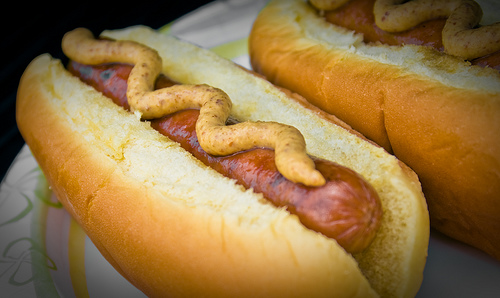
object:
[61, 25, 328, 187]
mustard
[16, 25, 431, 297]
bun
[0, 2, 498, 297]
plate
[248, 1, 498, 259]
bun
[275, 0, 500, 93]
edge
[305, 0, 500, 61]
mustard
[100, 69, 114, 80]
grill mark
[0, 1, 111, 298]
edge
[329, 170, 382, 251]
end